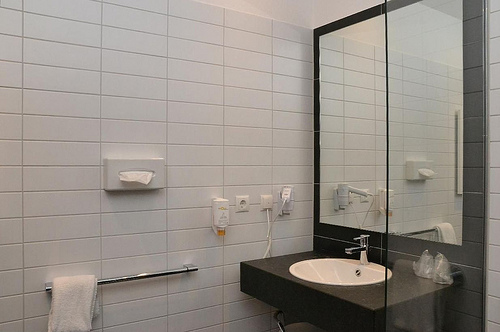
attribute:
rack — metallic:
[45, 264, 199, 291]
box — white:
[102, 155, 169, 191]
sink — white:
[289, 256, 395, 286]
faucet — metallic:
[347, 231, 372, 262]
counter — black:
[239, 248, 461, 327]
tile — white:
[100, 93, 169, 121]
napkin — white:
[117, 170, 156, 185]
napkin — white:
[119, 170, 155, 181]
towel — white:
[48, 274, 98, 330]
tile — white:
[23, 10, 102, 46]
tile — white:
[21, 61, 103, 93]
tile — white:
[21, 34, 102, 70]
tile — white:
[99, 48, 169, 77]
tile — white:
[21, 113, 102, 144]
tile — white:
[21, 103, 79, 212]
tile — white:
[21, 116, 91, 226]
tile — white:
[25, 125, 93, 224]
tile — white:
[28, 108, 104, 211]